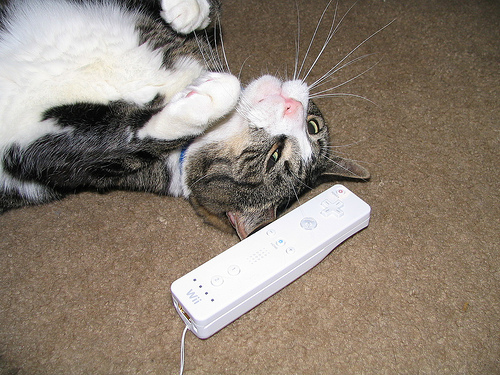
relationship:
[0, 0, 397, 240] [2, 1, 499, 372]
cat laying on floor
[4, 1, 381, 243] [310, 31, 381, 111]
cat has whiskers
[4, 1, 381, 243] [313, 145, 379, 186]
cat has ear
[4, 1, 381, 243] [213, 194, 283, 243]
cat has ear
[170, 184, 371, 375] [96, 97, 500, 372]
controller on th floor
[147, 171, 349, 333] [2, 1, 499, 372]
controller on floor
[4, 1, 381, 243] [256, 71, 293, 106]
cat has mouth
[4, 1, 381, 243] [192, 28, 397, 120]
cat has whiskers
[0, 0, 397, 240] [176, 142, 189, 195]
cat wearing collar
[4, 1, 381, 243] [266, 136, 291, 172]
cat has eye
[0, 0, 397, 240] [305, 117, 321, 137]
cat has eye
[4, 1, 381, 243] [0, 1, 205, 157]
cat has cat fur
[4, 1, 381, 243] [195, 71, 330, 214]
cat has head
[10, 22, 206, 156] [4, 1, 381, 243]
cat fur on cat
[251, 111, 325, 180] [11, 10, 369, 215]
eyes on cat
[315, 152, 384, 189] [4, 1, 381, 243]
ear on cat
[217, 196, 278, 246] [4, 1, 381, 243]
ear on cat